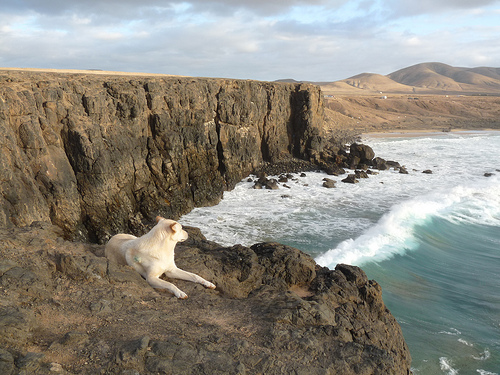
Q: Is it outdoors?
A: Yes, it is outdoors.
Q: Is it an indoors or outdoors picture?
A: It is outdoors.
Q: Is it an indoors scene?
A: No, it is outdoors.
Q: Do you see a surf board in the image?
A: No, there are no surfboards.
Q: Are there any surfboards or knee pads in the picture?
A: No, there are no surfboards or knee pads.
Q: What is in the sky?
A: The clouds are in the sky.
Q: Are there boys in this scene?
A: No, there are no boys.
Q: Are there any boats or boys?
A: No, there are no boys or boats.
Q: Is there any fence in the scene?
A: No, there are no fences.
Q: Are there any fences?
A: No, there are no fences.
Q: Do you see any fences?
A: No, there are no fences.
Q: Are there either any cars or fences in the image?
A: No, there are no fences or cars.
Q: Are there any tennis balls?
A: No, there are no tennis balls.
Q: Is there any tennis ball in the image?
A: No, there are no tennis balls.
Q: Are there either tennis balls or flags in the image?
A: No, there are no tennis balls or flags.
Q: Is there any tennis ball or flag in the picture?
A: No, there are no tennis balls or flags.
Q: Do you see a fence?
A: No, there are no fences.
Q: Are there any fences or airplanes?
A: No, there are no fences or airplanes.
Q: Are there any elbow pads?
A: No, there are no elbow pads.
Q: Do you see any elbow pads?
A: No, there are no elbow pads.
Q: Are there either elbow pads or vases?
A: No, there are no elbow pads or vases.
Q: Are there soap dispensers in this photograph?
A: No, there are no soap dispensers.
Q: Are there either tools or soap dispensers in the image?
A: No, there are no soap dispensers or tools.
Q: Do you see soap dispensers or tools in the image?
A: No, there are no soap dispensers or tools.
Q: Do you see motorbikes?
A: No, there are no motorbikes.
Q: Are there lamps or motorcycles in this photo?
A: No, there are no motorcycles or lamps.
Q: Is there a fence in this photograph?
A: No, there are no fences.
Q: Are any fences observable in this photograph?
A: No, there are no fences.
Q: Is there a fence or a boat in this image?
A: No, there are no fences or boats.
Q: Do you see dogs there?
A: Yes, there is a dog.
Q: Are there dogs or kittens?
A: Yes, there is a dog.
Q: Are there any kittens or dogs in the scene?
A: Yes, there is a dog.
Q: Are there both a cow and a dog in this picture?
A: No, there is a dog but no cows.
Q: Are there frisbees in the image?
A: No, there are no frisbees.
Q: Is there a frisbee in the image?
A: No, there are no frisbees.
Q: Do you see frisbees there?
A: No, there are no frisbees.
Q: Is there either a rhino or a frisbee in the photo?
A: No, there are no frisbees or rhinos.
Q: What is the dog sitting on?
A: The dog is sitting on the rocks.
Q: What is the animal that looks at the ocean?
A: The animal is a dog.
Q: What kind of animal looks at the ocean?
A: The animal is a dog.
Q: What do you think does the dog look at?
A: The dog looks at the ocean.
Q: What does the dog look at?
A: The dog looks at the ocean.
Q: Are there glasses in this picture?
A: No, there are no glasses.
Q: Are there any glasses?
A: No, there are no glasses.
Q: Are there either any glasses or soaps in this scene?
A: No, there are no glasses or soaps.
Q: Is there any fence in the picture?
A: No, there are no fences.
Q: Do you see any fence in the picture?
A: No, there are no fences.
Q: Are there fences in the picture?
A: No, there are no fences.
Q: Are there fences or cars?
A: No, there are no fences or cars.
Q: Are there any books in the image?
A: No, there are no books.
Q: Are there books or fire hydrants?
A: No, there are no books or fire hydrants.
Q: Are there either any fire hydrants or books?
A: No, there are no books or fire hydrants.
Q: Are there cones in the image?
A: No, there are no cones.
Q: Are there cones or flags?
A: No, there are no cones or flags.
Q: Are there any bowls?
A: No, there are no bowls.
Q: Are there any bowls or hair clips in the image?
A: No, there are no bowls or hair clips.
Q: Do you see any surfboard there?
A: No, there are no surfboards.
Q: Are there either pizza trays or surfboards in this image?
A: No, there are no surfboards or pizza trays.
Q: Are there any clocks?
A: No, there are no clocks.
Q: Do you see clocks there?
A: No, there are no clocks.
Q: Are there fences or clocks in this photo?
A: No, there are no clocks or fences.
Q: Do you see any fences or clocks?
A: No, there are no clocks or fences.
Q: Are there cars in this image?
A: No, there are no cars.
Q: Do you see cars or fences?
A: No, there are no cars or fences.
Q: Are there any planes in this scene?
A: No, there are no planes.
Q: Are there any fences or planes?
A: No, there are no planes or fences.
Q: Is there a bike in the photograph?
A: No, there are no bikes.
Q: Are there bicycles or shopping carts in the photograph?
A: No, there are no bicycles or shopping carts.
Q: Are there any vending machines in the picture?
A: No, there are no vending machines.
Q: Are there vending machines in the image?
A: No, there are no vending machines.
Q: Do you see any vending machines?
A: No, there are no vending machines.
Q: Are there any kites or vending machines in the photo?
A: No, there are no vending machines or kites.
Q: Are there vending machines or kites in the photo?
A: No, there are no vending machines or kites.